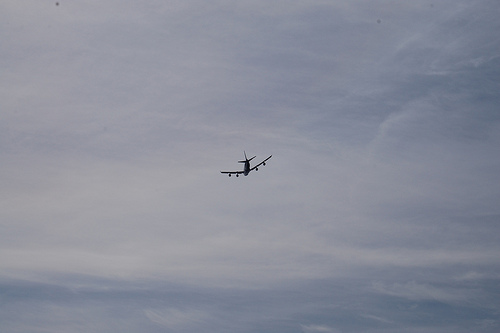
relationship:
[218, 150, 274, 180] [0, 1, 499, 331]
plane in sky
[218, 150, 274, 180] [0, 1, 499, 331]
plane flying in sky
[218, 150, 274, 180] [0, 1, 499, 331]
plane cruising in sky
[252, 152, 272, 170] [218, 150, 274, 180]
wing of a plane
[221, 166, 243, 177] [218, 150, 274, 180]
wing of a plane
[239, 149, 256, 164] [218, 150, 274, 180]
tail of a plane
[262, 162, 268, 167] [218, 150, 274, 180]
engine on a plane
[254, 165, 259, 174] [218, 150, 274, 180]
engine on a plane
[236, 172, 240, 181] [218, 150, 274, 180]
engine on a plane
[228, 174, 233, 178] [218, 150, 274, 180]
engine on a plane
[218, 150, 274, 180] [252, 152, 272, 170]
plane has a wing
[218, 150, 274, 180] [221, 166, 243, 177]
plane has a wing